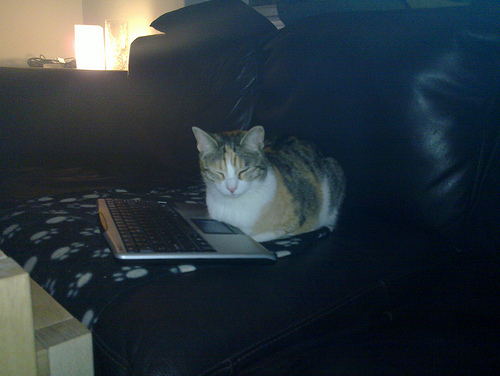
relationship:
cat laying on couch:
[186, 121, 348, 240] [1, 2, 498, 371]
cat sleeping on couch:
[186, 121, 348, 240] [1, 2, 498, 371]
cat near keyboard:
[186, 121, 348, 240] [116, 200, 195, 250]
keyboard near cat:
[116, 200, 195, 250] [186, 121, 348, 240]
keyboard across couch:
[116, 200, 195, 250] [1, 2, 498, 371]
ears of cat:
[188, 123, 267, 156] [186, 121, 348, 240]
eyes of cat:
[211, 165, 251, 179] [186, 121, 348, 240]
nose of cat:
[225, 183, 240, 197] [186, 121, 348, 240]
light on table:
[68, 16, 149, 78] [1, 53, 97, 81]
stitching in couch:
[210, 342, 257, 373] [1, 2, 498, 371]